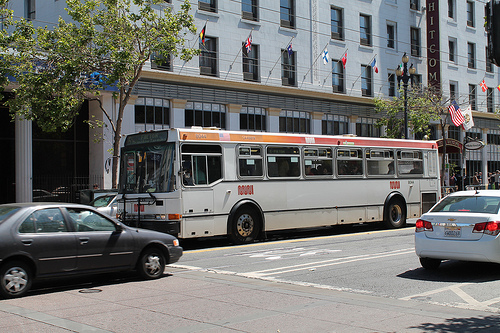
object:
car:
[1, 202, 182, 297]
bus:
[104, 125, 441, 244]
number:
[194, 133, 206, 139]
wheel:
[228, 205, 264, 245]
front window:
[119, 141, 176, 194]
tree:
[0, 0, 201, 189]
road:
[0, 213, 500, 333]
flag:
[198, 26, 205, 44]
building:
[0, 0, 499, 208]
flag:
[241, 37, 253, 56]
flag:
[285, 44, 294, 57]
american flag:
[446, 102, 466, 127]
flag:
[320, 48, 328, 65]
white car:
[414, 187, 500, 270]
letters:
[226, 245, 341, 260]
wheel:
[141, 253, 166, 279]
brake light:
[415, 219, 423, 230]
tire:
[386, 202, 405, 227]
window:
[239, 158, 263, 176]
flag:
[368, 59, 379, 75]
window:
[267, 155, 302, 178]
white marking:
[166, 264, 367, 293]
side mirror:
[116, 224, 122, 231]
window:
[180, 153, 221, 187]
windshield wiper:
[147, 190, 158, 204]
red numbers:
[237, 185, 252, 195]